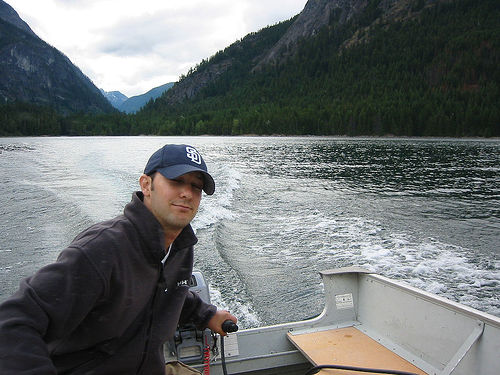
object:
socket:
[331, 290, 358, 310]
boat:
[188, 270, 500, 375]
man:
[6, 137, 252, 374]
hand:
[210, 309, 238, 341]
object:
[221, 317, 239, 333]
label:
[175, 279, 191, 289]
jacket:
[40, 197, 196, 368]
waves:
[210, 205, 279, 310]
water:
[210, 142, 497, 278]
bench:
[292, 333, 410, 374]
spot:
[341, 331, 358, 343]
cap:
[146, 143, 220, 196]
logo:
[183, 146, 205, 166]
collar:
[123, 200, 168, 258]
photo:
[5, 4, 499, 370]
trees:
[163, 94, 477, 136]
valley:
[80, 64, 182, 142]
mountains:
[264, 1, 492, 138]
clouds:
[114, 58, 163, 84]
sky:
[38, 5, 237, 56]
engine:
[192, 270, 214, 314]